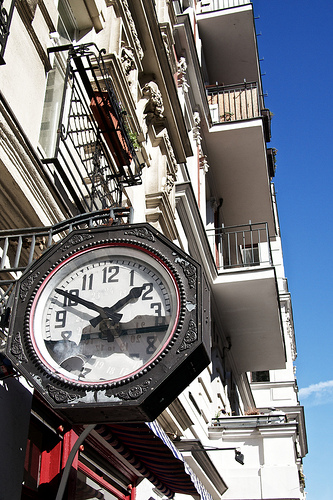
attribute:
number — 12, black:
[103, 264, 117, 283]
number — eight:
[51, 332, 73, 353]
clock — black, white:
[5, 223, 211, 418]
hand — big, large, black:
[49, 286, 122, 324]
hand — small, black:
[92, 285, 143, 327]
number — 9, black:
[52, 308, 69, 329]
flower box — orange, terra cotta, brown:
[86, 83, 134, 173]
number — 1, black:
[127, 267, 139, 285]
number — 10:
[61, 286, 80, 306]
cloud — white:
[301, 384, 333, 399]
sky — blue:
[296, 6, 332, 498]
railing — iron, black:
[208, 81, 262, 121]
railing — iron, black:
[213, 225, 272, 276]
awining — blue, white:
[97, 423, 219, 498]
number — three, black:
[149, 303, 161, 318]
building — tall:
[4, 5, 309, 498]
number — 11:
[81, 275, 93, 291]